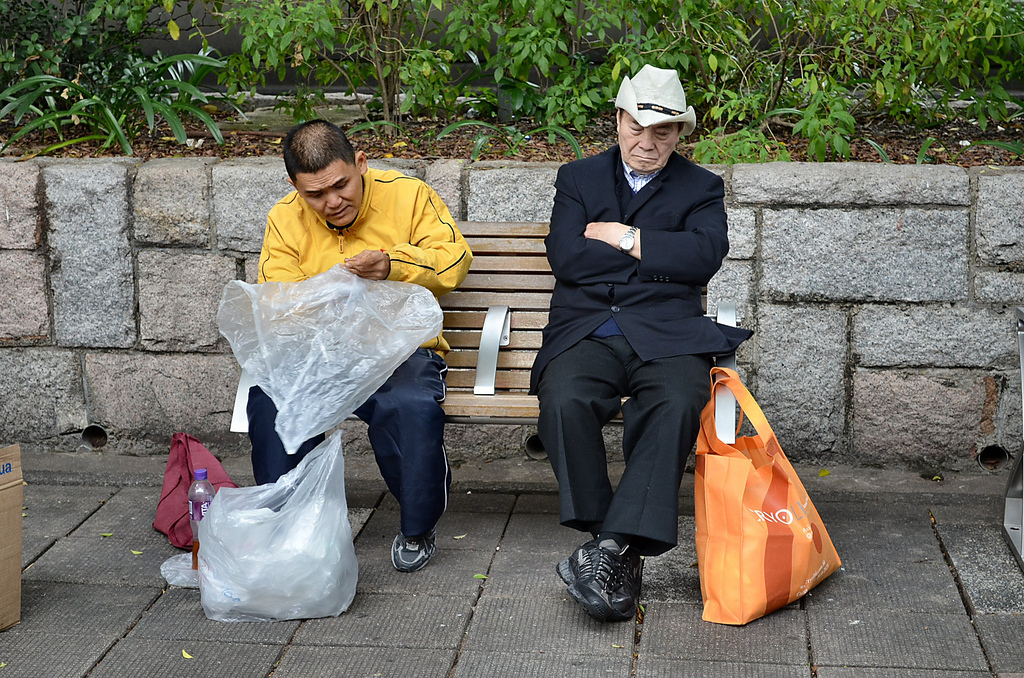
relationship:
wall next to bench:
[8, 150, 993, 494] [234, 214, 722, 442]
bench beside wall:
[234, 214, 722, 442] [8, 150, 993, 494]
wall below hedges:
[8, 150, 993, 494] [4, 4, 1023, 166]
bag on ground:
[694, 364, 850, 622] [37, 447, 986, 674]